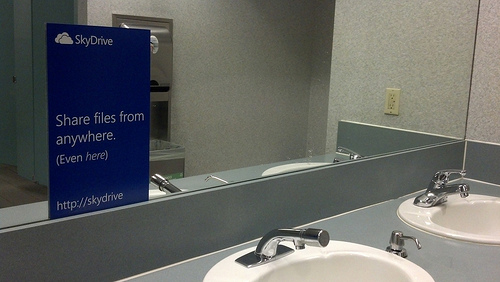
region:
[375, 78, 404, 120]
the socket in the wall is reflecting in the mirror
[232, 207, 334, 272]
the faucet is metal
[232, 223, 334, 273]
the faucet is silver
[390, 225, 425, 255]
the soap dispenser is metal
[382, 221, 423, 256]
the soap dispensor is silver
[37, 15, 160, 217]
the sign is blue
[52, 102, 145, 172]
the words are white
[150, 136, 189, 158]
the bag is plastic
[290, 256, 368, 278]
the sink is white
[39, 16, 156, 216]
the sign is rectangular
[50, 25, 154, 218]
blue sign with white letters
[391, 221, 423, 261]
soap dispenser right of front sink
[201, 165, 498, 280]
white sinks with silver faucets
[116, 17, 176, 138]
silver paper towel dispenser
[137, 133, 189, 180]
trash can with clear trash bag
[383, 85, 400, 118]
outlet reflected in mirror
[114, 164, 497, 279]
white sink with gray counter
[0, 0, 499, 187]
light gray bathroom walls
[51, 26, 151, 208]
advertisement for SkyDrive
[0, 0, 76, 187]
bathroom stalls reflected in mirror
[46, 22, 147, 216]
sign on mirror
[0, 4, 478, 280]
large mirror in bathroom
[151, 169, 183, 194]
part of faucet reflecting in mirror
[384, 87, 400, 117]
outlet reflecting in mirror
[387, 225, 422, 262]
soap dispenser on counter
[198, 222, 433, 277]
white bathroom sink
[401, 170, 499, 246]
white bathroom sink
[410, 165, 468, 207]
silver bathroom faucet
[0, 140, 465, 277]
gray backsplash area of bathroom sink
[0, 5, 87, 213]
doorway reflected in mirror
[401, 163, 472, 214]
silver bathroom faucet on sink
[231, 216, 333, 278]
silver bathroom faucet on sink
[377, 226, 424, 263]
silver metal soap dispenser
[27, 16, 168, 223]
blue and white sign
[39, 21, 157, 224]
blue sign on mirror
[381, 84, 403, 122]
reflection of electrical outlet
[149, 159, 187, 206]
reflection of a faucet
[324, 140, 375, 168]
reflection of a faucet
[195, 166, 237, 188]
relfection of soap dispenser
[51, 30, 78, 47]
white cloud painted on sign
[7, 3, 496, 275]
Nobody in the photo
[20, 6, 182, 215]
Blue sign on the mirror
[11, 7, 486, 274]
Scene takes place in a bathroom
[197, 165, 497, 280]
Two sinks in the bathroom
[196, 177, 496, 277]
The sinks are white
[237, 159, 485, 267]
The faucets are silver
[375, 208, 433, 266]
Silver soap dispenser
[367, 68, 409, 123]
Reflection of an electrical outlet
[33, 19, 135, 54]
SkyDrive advertisement on the mirror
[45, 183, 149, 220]
http://skydrive on the blue sign